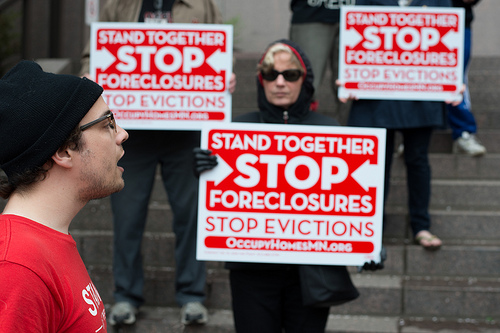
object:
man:
[1, 53, 136, 332]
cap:
[0, 55, 113, 194]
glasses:
[64, 101, 128, 145]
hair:
[254, 37, 309, 83]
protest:
[205, 151, 378, 240]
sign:
[188, 115, 392, 273]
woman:
[175, 31, 380, 332]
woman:
[328, 1, 460, 256]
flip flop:
[405, 221, 449, 255]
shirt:
[1, 208, 110, 332]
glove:
[188, 135, 223, 179]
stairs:
[61, 266, 500, 320]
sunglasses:
[255, 62, 311, 88]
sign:
[329, 2, 473, 113]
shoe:
[446, 127, 489, 161]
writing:
[79, 278, 111, 332]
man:
[79, 1, 241, 332]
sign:
[83, 18, 240, 146]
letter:
[113, 41, 138, 78]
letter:
[132, 41, 159, 79]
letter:
[152, 42, 187, 78]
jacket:
[197, 35, 367, 312]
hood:
[244, 32, 321, 123]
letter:
[178, 41, 209, 77]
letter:
[233, 148, 264, 195]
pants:
[353, 117, 444, 241]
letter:
[256, 147, 291, 193]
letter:
[284, 148, 325, 197]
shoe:
[102, 285, 146, 332]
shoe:
[170, 289, 216, 330]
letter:
[316, 152, 353, 197]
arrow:
[204, 44, 233, 79]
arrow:
[95, 41, 116, 74]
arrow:
[346, 153, 379, 196]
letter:
[204, 208, 218, 237]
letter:
[244, 212, 264, 237]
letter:
[259, 212, 280, 240]